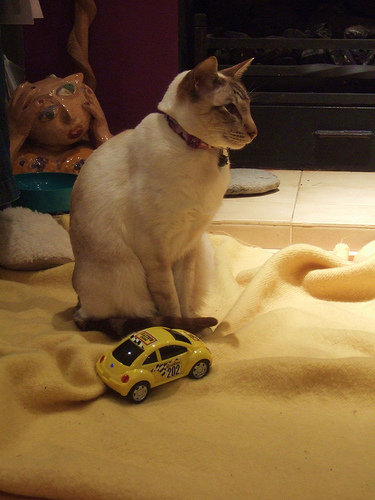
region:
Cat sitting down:
[60, 51, 268, 338]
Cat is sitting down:
[54, 51, 262, 336]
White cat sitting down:
[69, 48, 261, 339]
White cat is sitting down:
[67, 51, 259, 333]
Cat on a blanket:
[62, 51, 257, 333]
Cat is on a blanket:
[65, 49, 257, 337]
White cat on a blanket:
[61, 48, 256, 336]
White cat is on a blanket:
[63, 51, 257, 339]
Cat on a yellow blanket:
[70, 50, 258, 346]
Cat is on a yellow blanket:
[64, 50, 261, 337]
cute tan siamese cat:
[54, 52, 264, 334]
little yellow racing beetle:
[91, 322, 213, 407]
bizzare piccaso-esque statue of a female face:
[4, 64, 114, 174]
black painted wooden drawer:
[228, 101, 372, 195]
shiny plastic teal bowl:
[8, 168, 79, 213]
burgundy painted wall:
[0, 0, 178, 139]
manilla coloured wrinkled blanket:
[3, 225, 374, 497]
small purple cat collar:
[157, 106, 218, 155]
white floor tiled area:
[199, 159, 373, 254]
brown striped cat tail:
[79, 307, 220, 340]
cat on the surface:
[61, 54, 273, 326]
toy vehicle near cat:
[83, 326, 222, 402]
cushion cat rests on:
[15, 227, 370, 498]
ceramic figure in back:
[12, 69, 104, 173]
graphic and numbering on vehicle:
[154, 361, 195, 380]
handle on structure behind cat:
[312, 111, 370, 144]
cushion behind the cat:
[4, 201, 75, 269]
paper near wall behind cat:
[0, 3, 55, 23]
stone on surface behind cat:
[225, 166, 284, 196]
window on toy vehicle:
[119, 341, 135, 360]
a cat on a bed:
[54, 77, 247, 339]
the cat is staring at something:
[150, 46, 276, 161]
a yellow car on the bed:
[64, 242, 234, 418]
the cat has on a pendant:
[165, 121, 237, 179]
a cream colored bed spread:
[210, 242, 367, 484]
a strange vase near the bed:
[13, 66, 110, 188]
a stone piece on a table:
[209, 161, 286, 210]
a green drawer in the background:
[184, 7, 370, 169]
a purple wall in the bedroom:
[59, 5, 174, 83]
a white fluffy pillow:
[0, 201, 76, 283]